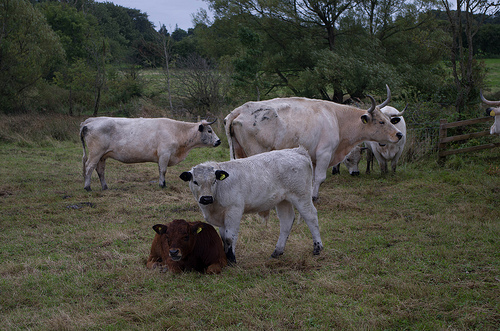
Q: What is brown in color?
A: A cow.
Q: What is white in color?
A: The cow.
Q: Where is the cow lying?
A: Lying in the grass.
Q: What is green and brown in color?
A: Grass.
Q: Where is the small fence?
A: Side of the cows.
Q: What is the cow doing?
A: Resting.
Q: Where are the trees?
A: Behind the cows.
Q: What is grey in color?
A: Horn of the cows.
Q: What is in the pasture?
A: A lot of cows.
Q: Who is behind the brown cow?
A: A white cow.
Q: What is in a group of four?
A: Cows.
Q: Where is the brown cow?
A: Laying on ground.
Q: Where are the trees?
A: Background.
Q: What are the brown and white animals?
A: Cows.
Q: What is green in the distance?
A: Cows.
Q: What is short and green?
A: Grass.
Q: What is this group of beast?
A: Cows.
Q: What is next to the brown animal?
A: White cow.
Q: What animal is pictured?
A: Cows.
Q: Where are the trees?
A: In background.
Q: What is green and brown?
A: Grass.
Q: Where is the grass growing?
A: On ground.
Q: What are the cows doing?
A: Standing.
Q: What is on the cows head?
A: Horns.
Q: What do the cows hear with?
A: Ears.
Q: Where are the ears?
A: On head.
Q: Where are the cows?
A: In field.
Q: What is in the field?
A: Cows.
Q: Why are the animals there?
A: Nature.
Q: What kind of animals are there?
A: Cow.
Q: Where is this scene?
A: Farm.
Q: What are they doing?
A: Chilling.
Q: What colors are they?
A: Brown and white.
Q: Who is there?
A: No one.